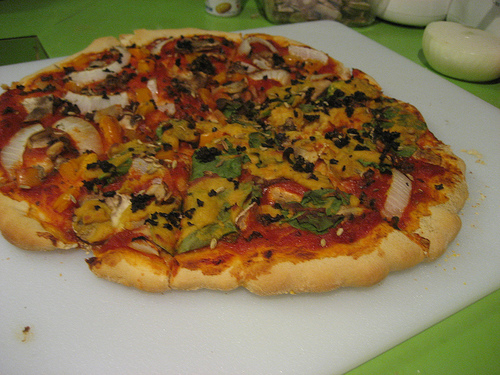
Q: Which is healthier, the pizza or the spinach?
A: The spinach is healthier than the pizza.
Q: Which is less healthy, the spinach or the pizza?
A: The pizza is less healthy than the spinach.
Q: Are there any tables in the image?
A: Yes, there is a table.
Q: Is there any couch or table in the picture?
A: Yes, there is a table.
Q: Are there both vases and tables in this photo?
A: No, there is a table but no vases.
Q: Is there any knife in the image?
A: No, there are no knives.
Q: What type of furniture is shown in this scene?
A: The furniture is a table.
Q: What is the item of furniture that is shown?
A: The piece of furniture is a table.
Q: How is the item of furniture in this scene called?
A: The piece of furniture is a table.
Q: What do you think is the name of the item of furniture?
A: The piece of furniture is a table.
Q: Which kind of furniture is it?
A: The piece of furniture is a table.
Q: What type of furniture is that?
A: This is a table.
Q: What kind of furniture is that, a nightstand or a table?
A: This is a table.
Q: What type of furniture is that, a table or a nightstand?
A: This is a table.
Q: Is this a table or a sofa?
A: This is a table.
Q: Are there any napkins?
A: No, there are no napkins.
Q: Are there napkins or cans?
A: No, there are no napkins or cans.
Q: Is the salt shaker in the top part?
A: Yes, the salt shaker is in the top of the image.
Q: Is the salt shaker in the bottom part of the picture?
A: No, the salt shaker is in the top of the image.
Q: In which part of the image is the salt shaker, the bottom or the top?
A: The salt shaker is in the top of the image.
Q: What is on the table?
A: The salt shaker is on the table.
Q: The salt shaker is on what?
A: The salt shaker is on the table.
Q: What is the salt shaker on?
A: The salt shaker is on the table.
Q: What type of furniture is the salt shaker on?
A: The salt shaker is on the table.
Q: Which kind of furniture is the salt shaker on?
A: The salt shaker is on the table.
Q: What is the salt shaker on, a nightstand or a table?
A: The salt shaker is on a table.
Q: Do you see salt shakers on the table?
A: Yes, there is a salt shaker on the table.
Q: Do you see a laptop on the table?
A: No, there is a salt shaker on the table.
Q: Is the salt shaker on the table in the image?
A: Yes, the salt shaker is on the table.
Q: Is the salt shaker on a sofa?
A: No, the salt shaker is on the table.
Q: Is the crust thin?
A: Yes, the crust is thin.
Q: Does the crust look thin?
A: Yes, the crust is thin.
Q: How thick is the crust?
A: The crust is thin.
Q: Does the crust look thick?
A: No, the crust is thin.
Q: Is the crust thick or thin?
A: The crust is thin.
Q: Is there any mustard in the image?
A: Yes, there is mustard.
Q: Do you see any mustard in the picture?
A: Yes, there is mustard.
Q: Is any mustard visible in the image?
A: Yes, there is mustard.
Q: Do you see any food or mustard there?
A: Yes, there is mustard.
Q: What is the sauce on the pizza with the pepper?
A: The sauce is mustard.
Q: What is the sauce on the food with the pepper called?
A: The sauce is mustard.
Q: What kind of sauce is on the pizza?
A: The sauce is mustard.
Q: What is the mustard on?
A: The mustard is on the pizza.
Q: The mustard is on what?
A: The mustard is on the pizza.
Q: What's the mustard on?
A: The mustard is on the pizza.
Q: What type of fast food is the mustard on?
A: The mustard is on the pizza.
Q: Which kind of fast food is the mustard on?
A: The mustard is on the pizza.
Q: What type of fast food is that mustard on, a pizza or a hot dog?
A: The mustard is on a pizza.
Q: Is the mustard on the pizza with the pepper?
A: Yes, the mustard is on the pizza.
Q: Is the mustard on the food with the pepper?
A: Yes, the mustard is on the pizza.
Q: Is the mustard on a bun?
A: No, the mustard is on the pizza.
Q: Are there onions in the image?
A: Yes, there is an onion.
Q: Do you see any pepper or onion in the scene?
A: Yes, there is an onion.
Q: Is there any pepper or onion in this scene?
A: Yes, there is an onion.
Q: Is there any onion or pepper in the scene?
A: Yes, there is an onion.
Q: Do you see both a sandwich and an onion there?
A: No, there is an onion but no sandwiches.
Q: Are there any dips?
A: No, there are no dips.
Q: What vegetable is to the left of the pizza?
A: The vegetable is an onion.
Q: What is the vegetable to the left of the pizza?
A: The vegetable is an onion.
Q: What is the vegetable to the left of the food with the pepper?
A: The vegetable is an onion.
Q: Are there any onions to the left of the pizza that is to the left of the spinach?
A: Yes, there is an onion to the left of the pizza.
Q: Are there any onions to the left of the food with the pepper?
A: Yes, there is an onion to the left of the pizza.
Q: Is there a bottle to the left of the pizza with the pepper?
A: No, there is an onion to the left of the pizza.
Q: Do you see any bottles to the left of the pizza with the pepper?
A: No, there is an onion to the left of the pizza.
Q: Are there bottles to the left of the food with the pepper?
A: No, there is an onion to the left of the pizza.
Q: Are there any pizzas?
A: Yes, there is a pizza.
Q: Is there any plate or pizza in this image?
A: Yes, there is a pizza.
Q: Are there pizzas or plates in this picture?
A: Yes, there is a pizza.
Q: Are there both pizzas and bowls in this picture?
A: No, there is a pizza but no bowls.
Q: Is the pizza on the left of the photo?
A: Yes, the pizza is on the left of the image.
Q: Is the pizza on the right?
A: No, the pizza is on the left of the image.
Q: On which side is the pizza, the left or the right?
A: The pizza is on the left of the image.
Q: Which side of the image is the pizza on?
A: The pizza is on the left of the image.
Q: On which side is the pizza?
A: The pizza is on the left of the image.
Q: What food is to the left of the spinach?
A: The food is a pizza.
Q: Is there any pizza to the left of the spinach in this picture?
A: Yes, there is a pizza to the left of the spinach.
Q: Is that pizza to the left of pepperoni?
A: No, the pizza is to the left of the spinach.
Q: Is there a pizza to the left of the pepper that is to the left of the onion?
A: Yes, there is a pizza to the left of the pepper.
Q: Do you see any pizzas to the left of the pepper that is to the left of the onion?
A: Yes, there is a pizza to the left of the pepper.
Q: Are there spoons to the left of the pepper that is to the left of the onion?
A: No, there is a pizza to the left of the pepper.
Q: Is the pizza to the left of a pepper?
A: Yes, the pizza is to the left of a pepper.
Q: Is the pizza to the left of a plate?
A: No, the pizza is to the left of a pepper.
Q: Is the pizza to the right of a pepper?
A: No, the pizza is to the left of a pepper.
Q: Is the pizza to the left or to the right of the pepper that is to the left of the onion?
A: The pizza is to the left of the pepper.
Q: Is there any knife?
A: No, there are no knives.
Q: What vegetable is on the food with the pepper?
A: The vegetable is spinach.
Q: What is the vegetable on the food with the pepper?
A: The vegetable is spinach.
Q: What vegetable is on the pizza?
A: The vegetable is spinach.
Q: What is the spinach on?
A: The spinach is on the pizza.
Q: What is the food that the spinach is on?
A: The food is a pizza.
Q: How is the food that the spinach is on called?
A: The food is a pizza.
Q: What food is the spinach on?
A: The spinach is on the pizza.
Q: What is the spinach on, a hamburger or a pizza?
A: The spinach is on a pizza.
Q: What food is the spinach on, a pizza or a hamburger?
A: The spinach is on a pizza.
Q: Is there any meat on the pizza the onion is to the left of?
A: No, there is spinach on the pizza.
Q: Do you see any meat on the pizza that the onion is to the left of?
A: No, there is spinach on the pizza.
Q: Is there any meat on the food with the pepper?
A: No, there is spinach on the pizza.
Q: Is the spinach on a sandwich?
A: No, the spinach is on the pizza.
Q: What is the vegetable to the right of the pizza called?
A: The vegetable is spinach.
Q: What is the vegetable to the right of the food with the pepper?
A: The vegetable is spinach.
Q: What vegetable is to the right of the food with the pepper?
A: The vegetable is spinach.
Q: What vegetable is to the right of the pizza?
A: The vegetable is spinach.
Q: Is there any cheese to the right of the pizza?
A: No, there is spinach to the right of the pizza.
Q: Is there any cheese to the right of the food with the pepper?
A: No, there is spinach to the right of the pizza.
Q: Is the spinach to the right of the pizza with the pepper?
A: Yes, the spinach is to the right of the pizza.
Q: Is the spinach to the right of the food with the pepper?
A: Yes, the spinach is to the right of the pizza.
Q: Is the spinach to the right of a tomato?
A: No, the spinach is to the right of the pizza.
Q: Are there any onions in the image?
A: Yes, there is an onion.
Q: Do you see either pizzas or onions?
A: Yes, there is an onion.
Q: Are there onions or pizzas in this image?
A: Yes, there is an onion.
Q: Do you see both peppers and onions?
A: Yes, there are both an onion and a pepper.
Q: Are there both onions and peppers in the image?
A: Yes, there are both an onion and a pepper.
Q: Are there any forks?
A: No, there are no forks.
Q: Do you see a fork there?
A: No, there are no forks.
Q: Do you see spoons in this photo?
A: No, there are no spoons.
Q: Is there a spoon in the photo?
A: No, there are no spoons.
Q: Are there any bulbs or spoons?
A: No, there are no spoons or bulbs.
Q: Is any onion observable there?
A: Yes, there is an onion.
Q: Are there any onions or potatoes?
A: Yes, there is an onion.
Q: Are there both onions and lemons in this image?
A: No, there is an onion but no lemons.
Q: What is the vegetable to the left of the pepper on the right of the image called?
A: The vegetable is an onion.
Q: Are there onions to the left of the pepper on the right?
A: Yes, there is an onion to the left of the pepper.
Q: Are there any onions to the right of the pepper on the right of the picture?
A: No, the onion is to the left of the pepper.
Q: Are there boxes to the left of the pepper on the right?
A: No, there is an onion to the left of the pepper.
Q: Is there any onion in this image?
A: Yes, there is an onion.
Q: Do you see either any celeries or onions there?
A: Yes, there is an onion.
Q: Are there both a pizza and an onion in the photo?
A: Yes, there are both an onion and a pizza.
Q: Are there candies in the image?
A: No, there are no candies.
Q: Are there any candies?
A: No, there are no candies.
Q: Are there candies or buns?
A: No, there are no candies or buns.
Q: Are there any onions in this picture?
A: Yes, there is an onion.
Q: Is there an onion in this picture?
A: Yes, there is an onion.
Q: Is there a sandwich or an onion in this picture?
A: Yes, there is an onion.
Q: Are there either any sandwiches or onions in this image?
A: Yes, there is an onion.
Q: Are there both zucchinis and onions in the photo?
A: No, there is an onion but no zucchinis.